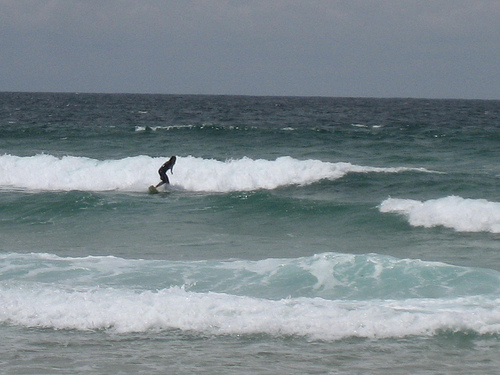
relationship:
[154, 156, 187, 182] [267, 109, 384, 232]
man on water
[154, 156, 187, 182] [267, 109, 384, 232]
man in water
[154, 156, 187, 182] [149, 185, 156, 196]
man on surfboard